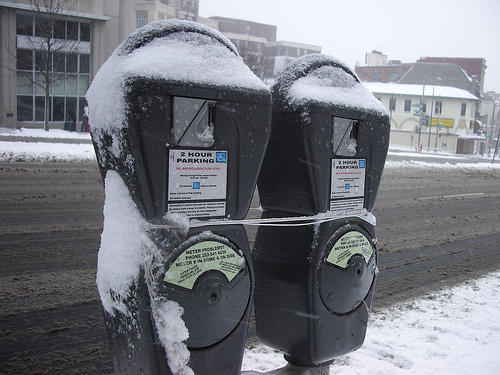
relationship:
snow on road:
[171, 266, 500, 375] [1, 156, 499, 369]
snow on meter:
[240, 267, 497, 372] [252, 51, 392, 373]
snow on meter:
[240, 267, 497, 372] [82, 17, 274, 374]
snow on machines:
[171, 266, 500, 375] [81, 83, 417, 375]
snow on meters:
[139, 45, 250, 81] [78, 9, 401, 374]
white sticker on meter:
[182, 139, 236, 206] [67, 9, 285, 374]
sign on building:
[424, 114, 454, 128] [350, 60, 487, 154]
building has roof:
[323, 39, 492, 234] [350, 56, 484, 88]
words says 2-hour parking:
[162, 142, 372, 202] [174, 147, 218, 164]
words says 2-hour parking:
[162, 142, 372, 202] [336, 160, 362, 172]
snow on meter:
[85, 164, 200, 375] [82, 17, 274, 374]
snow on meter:
[0, 78, 499, 173] [82, 17, 274, 374]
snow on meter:
[220, 272, 498, 369] [243, 50, 394, 375]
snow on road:
[171, 266, 500, 375] [7, 157, 498, 274]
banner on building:
[411, 99, 481, 146] [329, 23, 498, 195]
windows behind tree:
[6, 7, 119, 138] [22, 4, 84, 124]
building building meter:
[354, 78, 484, 166] [281, 60, 395, 340]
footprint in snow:
[374, 341, 408, 371] [419, 304, 489, 373]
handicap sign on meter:
[215, 151, 227, 164] [82, 17, 274, 374]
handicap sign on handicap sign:
[213, 150, 228, 162] [215, 151, 227, 164]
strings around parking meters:
[210, 187, 331, 238] [76, 12, 391, 363]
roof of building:
[359, 57, 489, 95] [355, 51, 482, 161]